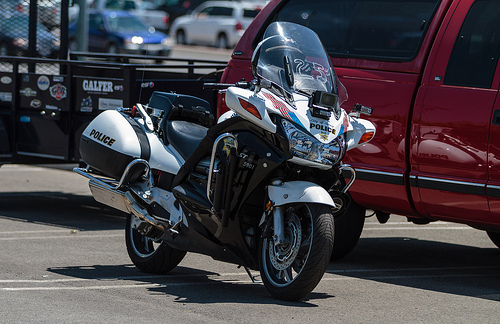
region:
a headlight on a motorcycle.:
[269, 108, 362, 170]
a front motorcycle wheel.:
[244, 198, 364, 291]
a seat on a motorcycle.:
[67, 83, 235, 213]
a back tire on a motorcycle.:
[107, 190, 203, 290]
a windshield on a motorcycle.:
[247, 20, 340, 102]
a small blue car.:
[63, 0, 181, 72]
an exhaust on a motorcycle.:
[81, 173, 200, 250]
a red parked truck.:
[227, 0, 497, 271]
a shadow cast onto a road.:
[1, 180, 133, 236]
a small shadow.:
[35, 253, 201, 297]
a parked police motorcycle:
[77, 29, 367, 296]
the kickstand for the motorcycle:
[234, 266, 259, 283]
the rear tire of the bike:
[122, 244, 194, 281]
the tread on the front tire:
[314, 212, 334, 261]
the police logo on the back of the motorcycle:
[83, 124, 121, 152]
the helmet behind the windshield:
[250, 23, 307, 78]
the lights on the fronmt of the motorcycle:
[305, 83, 342, 123]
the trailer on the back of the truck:
[5, 1, 69, 167]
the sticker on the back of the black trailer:
[0, 71, 75, 132]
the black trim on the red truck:
[375, 158, 499, 206]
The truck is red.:
[216, 0, 498, 257]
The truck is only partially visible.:
[218, 0, 498, 230]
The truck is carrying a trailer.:
[0, 0, 225, 160]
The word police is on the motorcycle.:
[88, 128, 117, 148]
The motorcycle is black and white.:
[72, 20, 374, 299]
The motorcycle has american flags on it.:
[261, 90, 349, 135]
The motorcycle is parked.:
[71, 19, 377, 301]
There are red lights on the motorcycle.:
[236, 93, 376, 147]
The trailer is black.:
[1, 1, 228, 162]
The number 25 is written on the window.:
[293, 54, 330, 84]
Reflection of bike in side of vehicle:
[355, 114, 499, 181]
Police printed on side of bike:
[88, 128, 117, 146]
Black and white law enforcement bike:
[72, 18, 378, 300]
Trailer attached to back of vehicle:
[1, 0, 232, 165]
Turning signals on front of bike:
[224, 86, 377, 151]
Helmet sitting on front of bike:
[248, 32, 308, 84]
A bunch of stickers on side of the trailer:
[1, 70, 128, 112]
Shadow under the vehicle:
[325, 235, 499, 305]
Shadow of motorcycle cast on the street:
[44, 258, 336, 308]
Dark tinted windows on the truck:
[248, 1, 499, 89]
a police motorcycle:
[57, 48, 361, 298]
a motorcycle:
[81, 43, 376, 272]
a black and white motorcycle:
[81, 42, 408, 270]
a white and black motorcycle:
[66, 50, 394, 285]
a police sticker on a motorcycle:
[63, 116, 128, 175]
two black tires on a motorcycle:
[111, 181, 391, 312]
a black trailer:
[0, 7, 232, 169]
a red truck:
[228, 5, 492, 254]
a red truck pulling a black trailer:
[20, 10, 484, 192]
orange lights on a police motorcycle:
[214, 86, 388, 161]